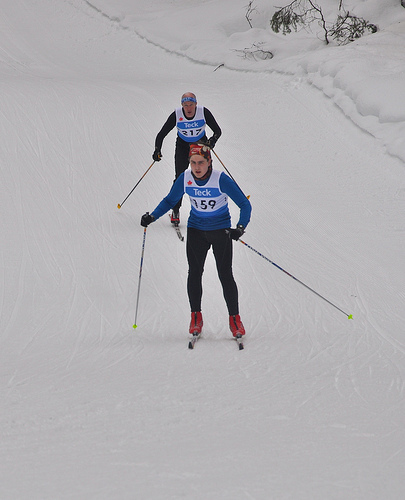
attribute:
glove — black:
[134, 207, 157, 236]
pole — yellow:
[110, 188, 161, 346]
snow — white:
[249, 60, 328, 122]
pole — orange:
[90, 154, 160, 221]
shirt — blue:
[148, 145, 262, 250]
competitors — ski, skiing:
[107, 52, 279, 376]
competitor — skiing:
[110, 154, 301, 344]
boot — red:
[178, 300, 226, 334]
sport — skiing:
[34, 54, 327, 499]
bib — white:
[188, 192, 227, 218]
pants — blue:
[156, 205, 243, 357]